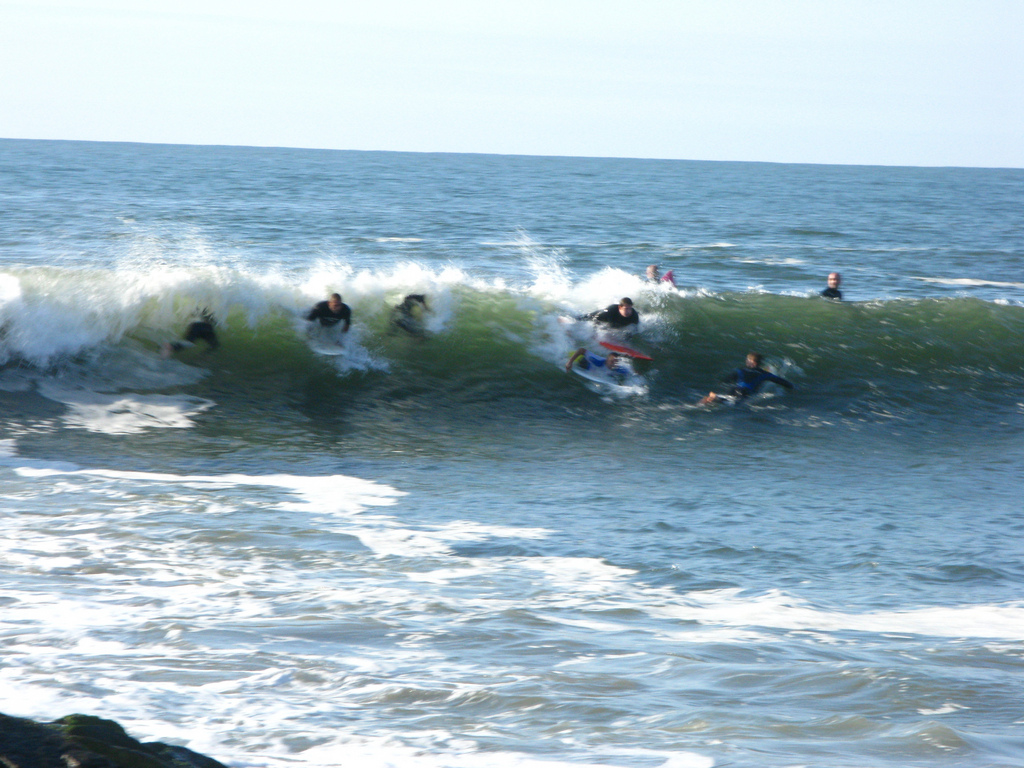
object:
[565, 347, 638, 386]
person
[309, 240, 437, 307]
foams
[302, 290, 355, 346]
man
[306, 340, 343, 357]
surfboard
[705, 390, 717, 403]
feet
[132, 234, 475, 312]
splash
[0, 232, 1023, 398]
wave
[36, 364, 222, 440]
foam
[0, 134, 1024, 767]
ocean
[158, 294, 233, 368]
surfers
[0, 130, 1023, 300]
water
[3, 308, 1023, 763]
water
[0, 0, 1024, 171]
sky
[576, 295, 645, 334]
people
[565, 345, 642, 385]
people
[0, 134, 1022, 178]
horizon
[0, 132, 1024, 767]
water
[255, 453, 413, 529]
breakers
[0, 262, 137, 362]
sea foam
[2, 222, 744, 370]
ocean waves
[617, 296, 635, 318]
head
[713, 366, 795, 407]
wetsuit